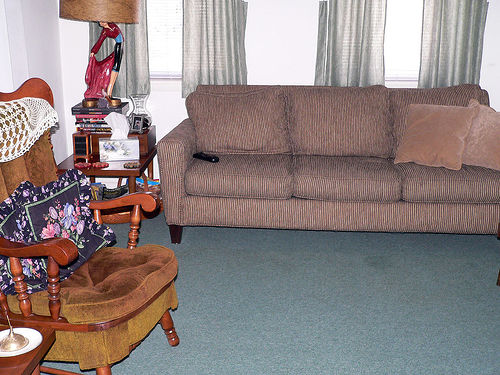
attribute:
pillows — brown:
[393, 101, 472, 175]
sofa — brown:
[157, 84, 499, 244]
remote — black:
[191, 149, 219, 168]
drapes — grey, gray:
[181, 0, 246, 88]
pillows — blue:
[1, 171, 114, 291]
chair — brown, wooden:
[1, 77, 179, 374]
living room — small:
[0, 2, 499, 373]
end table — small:
[57, 149, 155, 199]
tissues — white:
[98, 110, 140, 164]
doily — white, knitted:
[2, 97, 59, 163]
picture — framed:
[130, 115, 144, 134]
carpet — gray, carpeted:
[178, 244, 499, 372]